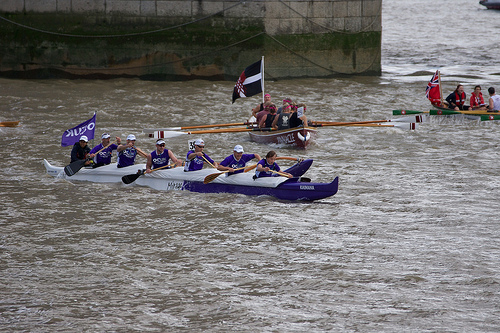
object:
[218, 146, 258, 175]
man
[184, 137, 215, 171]
man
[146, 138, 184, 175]
man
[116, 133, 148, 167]
man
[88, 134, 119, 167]
man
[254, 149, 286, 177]
woman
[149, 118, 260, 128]
oar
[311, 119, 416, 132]
oar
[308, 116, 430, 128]
oar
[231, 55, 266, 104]
flag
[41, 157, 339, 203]
kayak